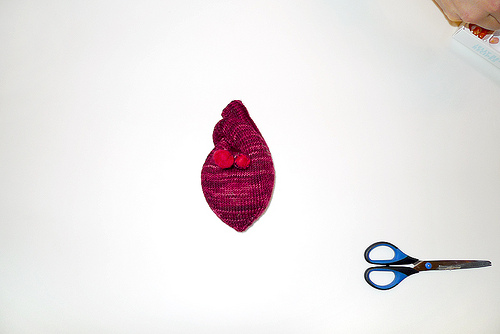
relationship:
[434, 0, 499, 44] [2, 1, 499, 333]
hand on table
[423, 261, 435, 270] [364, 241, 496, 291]
screw on scissors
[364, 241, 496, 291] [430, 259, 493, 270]
scissors have long part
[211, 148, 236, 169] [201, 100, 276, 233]
ball on cloth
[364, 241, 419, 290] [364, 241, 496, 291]
outline on scissors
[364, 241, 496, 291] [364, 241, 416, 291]
scissors have handle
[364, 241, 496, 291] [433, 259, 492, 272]
scissors have blade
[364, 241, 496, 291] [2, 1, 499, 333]
scissors on top of table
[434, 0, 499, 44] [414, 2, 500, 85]
hand in corner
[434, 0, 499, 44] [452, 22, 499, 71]
hand holding something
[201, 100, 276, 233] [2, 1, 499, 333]
cloth in middle of photo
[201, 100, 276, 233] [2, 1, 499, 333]
cloth on top of table